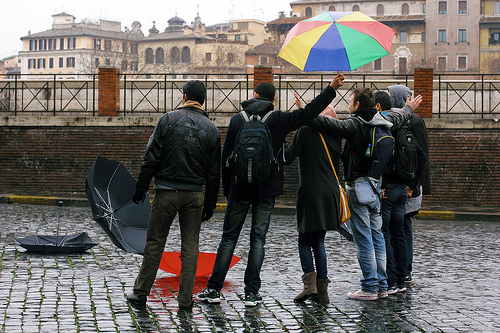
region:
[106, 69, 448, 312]
a group on your people standing on a wet road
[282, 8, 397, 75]
a multi-colored umbrella being held in the air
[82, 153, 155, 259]
a black umbrella flipped over on the ground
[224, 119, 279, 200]
a black backpack one of the young men is wearing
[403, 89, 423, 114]
the hand of one of the people held in the air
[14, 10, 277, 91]
large historic buildings in the distance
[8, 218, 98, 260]
a black umbrella upside down on the wet brick road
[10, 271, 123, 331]
wet cobblestone bricks on the road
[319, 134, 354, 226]
an orange and yellow sling bag a young lady is wearing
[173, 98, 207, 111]
a tan colored scarf around the neck of one of the young men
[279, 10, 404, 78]
a colorful open umbrella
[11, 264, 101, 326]
a brick walkway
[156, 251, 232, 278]
a red umbrella upside down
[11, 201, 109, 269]
an upside down black umbrella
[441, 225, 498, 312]
wet bricks on the ground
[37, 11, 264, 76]
a row of buildings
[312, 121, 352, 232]
a brown purse on a woman's shoulder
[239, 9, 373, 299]
a man holding an umbrella over a woman's head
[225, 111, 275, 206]
a black and grey backpack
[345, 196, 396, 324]
blue jeans on a man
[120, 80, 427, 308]
A group of people standing together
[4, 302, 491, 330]
A cobble stone walkway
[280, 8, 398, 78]
A mulit-colored umbrella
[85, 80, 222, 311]
A man holding a black umbrella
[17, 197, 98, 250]
A black umbrella upside down on the ground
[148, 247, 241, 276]
A red umbrella upside down on the ground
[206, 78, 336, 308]
A man wearing a black backpack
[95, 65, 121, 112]
A brick portion of a fence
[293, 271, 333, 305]
A woman's brown boots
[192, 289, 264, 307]
A man's black and white shoes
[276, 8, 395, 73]
Umbrella being held is colorful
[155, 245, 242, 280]
Umbrella on floor is red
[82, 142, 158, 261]
Umbrella pointing down being held by man is black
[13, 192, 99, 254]
Umbrella on floor is black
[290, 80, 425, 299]
Man extending his arms out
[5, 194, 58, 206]
Yellow painting on sidewalk curb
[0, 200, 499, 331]
Floor is wet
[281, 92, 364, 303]
Woman wearing tan satchel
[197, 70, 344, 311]
Man wearing backpack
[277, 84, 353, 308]
Woman wearing brown boots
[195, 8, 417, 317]
Man is holding a multicolored umbrella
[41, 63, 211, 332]
Man is holding a black umbrella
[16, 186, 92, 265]
Black umbrella on the ground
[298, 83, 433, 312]
Man with backpack on his back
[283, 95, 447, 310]
Man with backpack on his back with his arms out at his sides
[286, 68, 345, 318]
Woman in a hat and boots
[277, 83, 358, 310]
A woman in boots with a bag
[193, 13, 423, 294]
Man carrying backpack has umbrella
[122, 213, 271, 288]
Red umbrella on the ground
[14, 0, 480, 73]
Buildings in the distance